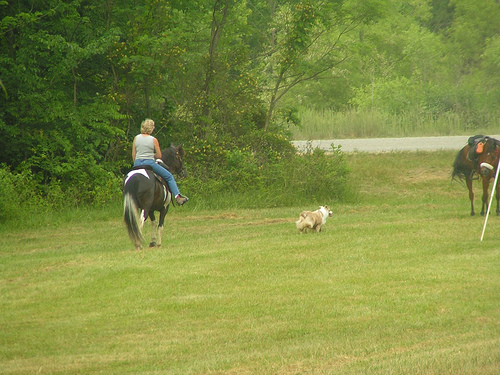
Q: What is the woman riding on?
A: She is on a horse.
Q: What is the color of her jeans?
A: She is wearing blue jeans.